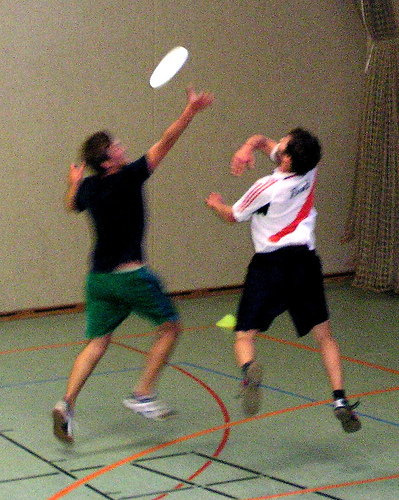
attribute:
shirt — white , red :
[231, 171, 321, 246]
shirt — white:
[234, 178, 318, 241]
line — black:
[132, 460, 200, 488]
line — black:
[46, 457, 63, 469]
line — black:
[120, 471, 267, 497]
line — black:
[0, 470, 59, 482]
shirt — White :
[230, 167, 321, 251]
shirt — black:
[76, 171, 151, 271]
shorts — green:
[79, 264, 179, 338]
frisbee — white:
[133, 30, 197, 75]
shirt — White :
[226, 166, 325, 253]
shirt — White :
[231, 141, 323, 244]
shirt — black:
[67, 152, 153, 273]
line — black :
[186, 433, 250, 497]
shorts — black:
[231, 246, 330, 337]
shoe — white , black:
[326, 385, 363, 431]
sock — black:
[228, 361, 259, 378]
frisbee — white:
[129, 31, 201, 93]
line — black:
[314, 488, 347, 498]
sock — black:
[329, 385, 346, 403]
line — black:
[132, 448, 198, 462]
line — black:
[117, 469, 259, 497]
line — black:
[0, 444, 195, 482]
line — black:
[0, 430, 115, 497]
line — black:
[133, 461, 233, 497]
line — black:
[132, 449, 190, 462]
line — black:
[68, 461, 104, 471]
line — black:
[191, 445, 343, 497]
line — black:
[112, 472, 259, 498]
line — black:
[129, 448, 194, 464]